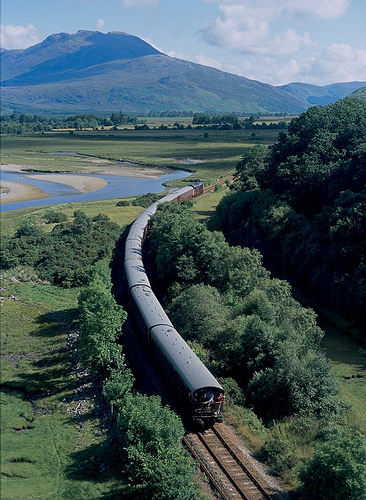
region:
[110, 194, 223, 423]
gray train cars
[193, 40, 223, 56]
white clouds in blue sky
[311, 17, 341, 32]
white clouds in blue sky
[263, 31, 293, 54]
white clouds in blue sky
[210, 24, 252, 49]
white clouds in blue sky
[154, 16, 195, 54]
white clouds in blue sky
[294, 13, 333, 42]
white clouds in blue sky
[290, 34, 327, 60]
white clouds in blue sky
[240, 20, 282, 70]
white clouds in blue sky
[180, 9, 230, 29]
white clouds in blue sky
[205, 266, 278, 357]
trees covered in green leaves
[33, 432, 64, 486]
green grass growing beside train tracks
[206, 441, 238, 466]
brown metal train tracks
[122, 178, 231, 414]
long silver train on tracks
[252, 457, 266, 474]
grey gravel beside train tracks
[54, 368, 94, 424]
grey rocks covering ground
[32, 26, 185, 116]
large grassy mountainside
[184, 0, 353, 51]
large white cloud in sky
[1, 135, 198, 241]
small pond beside train tracks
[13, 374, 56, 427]
hole in ground beside train tracks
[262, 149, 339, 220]
trees in the photo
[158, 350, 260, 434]
front of the train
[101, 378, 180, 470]
trees next to train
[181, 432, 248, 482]
track under the train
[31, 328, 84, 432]
shadows on the ground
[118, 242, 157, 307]
top of the train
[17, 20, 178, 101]
hill in the distance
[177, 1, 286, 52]
sky above the land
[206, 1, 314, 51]
clouds in the sky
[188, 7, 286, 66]
white clouds in sky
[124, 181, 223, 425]
Train traveling down tracks through countryside.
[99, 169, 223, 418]
a long train travels through the countryside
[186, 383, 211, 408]
people stand on back balcony of last train car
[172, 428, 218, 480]
train track strewn with stones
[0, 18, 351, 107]
a tall tree covered hill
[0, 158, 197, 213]
water for irrigation of fields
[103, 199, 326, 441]
trees and brush frame the train tracks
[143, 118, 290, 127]
a plowed field in the distance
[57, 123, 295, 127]
a tree line seperates two fields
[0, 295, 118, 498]
shadows are cast by the desk on trees and bushes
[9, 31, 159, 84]
shadow of a hill lies over the mountian